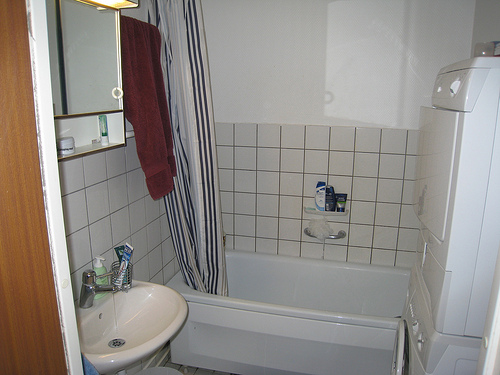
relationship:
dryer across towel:
[413, 55, 500, 338] [119, 14, 178, 201]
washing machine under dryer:
[391, 258, 482, 374] [413, 55, 500, 338]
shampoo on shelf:
[326, 185, 337, 211] [303, 207, 350, 217]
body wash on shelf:
[314, 181, 328, 212] [303, 207, 350, 217]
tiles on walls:
[58, 121, 422, 285] [46, 0, 476, 375]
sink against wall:
[72, 279, 190, 374] [46, 0, 184, 374]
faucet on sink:
[80, 270, 119, 308] [72, 279, 190, 374]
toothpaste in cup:
[118, 242, 134, 290] [110, 261, 134, 291]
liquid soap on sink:
[95, 255, 111, 299] [72, 279, 190, 374]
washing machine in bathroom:
[391, 258, 482, 374] [45, 0, 499, 374]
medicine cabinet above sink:
[46, 0, 127, 163] [72, 279, 190, 374]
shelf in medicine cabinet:
[52, 111, 128, 164] [46, 0, 127, 163]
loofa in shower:
[307, 217, 334, 243] [164, 0, 477, 375]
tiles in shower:
[58, 121, 422, 285] [164, 0, 477, 375]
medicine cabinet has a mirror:
[46, 0, 127, 163] [45, 1, 123, 117]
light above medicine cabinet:
[79, 0, 140, 11] [46, 0, 127, 163]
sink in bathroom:
[72, 279, 190, 374] [45, 0, 499, 374]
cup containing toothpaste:
[110, 261, 134, 291] [118, 242, 134, 290]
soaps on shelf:
[306, 181, 347, 213] [303, 207, 350, 217]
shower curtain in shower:
[145, 0, 229, 297] [164, 0, 477, 375]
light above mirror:
[79, 0, 140, 11] [45, 1, 123, 117]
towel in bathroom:
[119, 14, 178, 201] [45, 0, 499, 374]